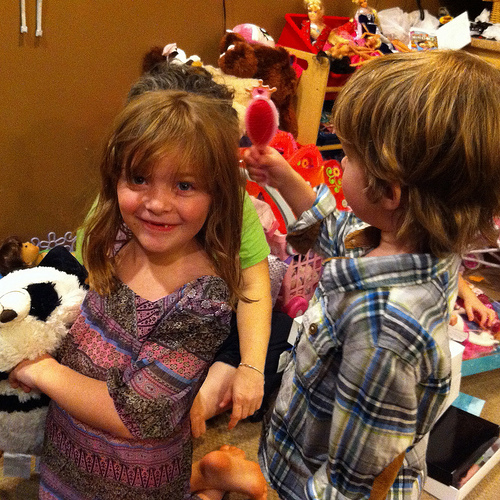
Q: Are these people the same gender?
A: No, they are both male and female.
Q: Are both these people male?
A: No, they are both male and female.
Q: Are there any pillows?
A: No, there are no pillows.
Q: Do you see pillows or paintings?
A: No, there are no pillows or paintings.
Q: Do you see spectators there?
A: No, there are no spectators.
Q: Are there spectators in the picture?
A: No, there are no spectators.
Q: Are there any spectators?
A: No, there are no spectators.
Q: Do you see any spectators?
A: No, there are no spectators.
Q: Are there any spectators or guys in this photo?
A: No, there are no spectators or guys.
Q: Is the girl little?
A: Yes, the girl is little.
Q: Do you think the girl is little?
A: Yes, the girl is little.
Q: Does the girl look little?
A: Yes, the girl is little.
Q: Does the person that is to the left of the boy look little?
A: Yes, the girl is little.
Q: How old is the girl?
A: The girl is little.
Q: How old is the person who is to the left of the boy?
A: The girl is little.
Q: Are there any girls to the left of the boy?
A: Yes, there is a girl to the left of the boy.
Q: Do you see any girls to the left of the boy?
A: Yes, there is a girl to the left of the boy.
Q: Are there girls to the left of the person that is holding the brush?
A: Yes, there is a girl to the left of the boy.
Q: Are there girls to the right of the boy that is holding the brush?
A: No, the girl is to the left of the boy.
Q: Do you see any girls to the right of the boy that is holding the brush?
A: No, the girl is to the left of the boy.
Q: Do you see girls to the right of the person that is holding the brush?
A: No, the girl is to the left of the boy.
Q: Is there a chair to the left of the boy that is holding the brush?
A: No, there is a girl to the left of the boy.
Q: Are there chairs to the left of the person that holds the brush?
A: No, there is a girl to the left of the boy.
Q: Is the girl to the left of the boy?
A: Yes, the girl is to the left of the boy.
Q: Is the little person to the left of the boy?
A: Yes, the girl is to the left of the boy.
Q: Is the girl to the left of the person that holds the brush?
A: Yes, the girl is to the left of the boy.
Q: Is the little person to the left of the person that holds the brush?
A: Yes, the girl is to the left of the boy.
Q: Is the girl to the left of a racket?
A: No, the girl is to the left of the boy.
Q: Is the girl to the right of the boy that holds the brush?
A: No, the girl is to the left of the boy.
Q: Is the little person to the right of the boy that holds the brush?
A: No, the girl is to the left of the boy.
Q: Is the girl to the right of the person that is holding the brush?
A: No, the girl is to the left of the boy.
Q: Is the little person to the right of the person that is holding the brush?
A: No, the girl is to the left of the boy.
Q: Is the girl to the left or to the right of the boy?
A: The girl is to the left of the boy.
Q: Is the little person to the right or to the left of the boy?
A: The girl is to the left of the boy.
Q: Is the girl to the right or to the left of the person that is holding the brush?
A: The girl is to the left of the boy.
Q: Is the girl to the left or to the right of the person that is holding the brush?
A: The girl is to the left of the boy.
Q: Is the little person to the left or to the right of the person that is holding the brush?
A: The girl is to the left of the boy.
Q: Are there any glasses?
A: No, there are no glasses.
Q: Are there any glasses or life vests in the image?
A: No, there are no glasses or life vests.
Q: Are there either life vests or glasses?
A: No, there are no glasses or life vests.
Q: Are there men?
A: No, there are no men.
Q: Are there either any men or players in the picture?
A: No, there are no men or players.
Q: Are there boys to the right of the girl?
A: Yes, there is a boy to the right of the girl.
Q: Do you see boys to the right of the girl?
A: Yes, there is a boy to the right of the girl.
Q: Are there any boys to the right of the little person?
A: Yes, there is a boy to the right of the girl.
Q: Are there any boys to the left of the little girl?
A: No, the boy is to the right of the girl.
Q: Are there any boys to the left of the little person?
A: No, the boy is to the right of the girl.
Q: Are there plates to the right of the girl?
A: No, there is a boy to the right of the girl.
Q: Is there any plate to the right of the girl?
A: No, there is a boy to the right of the girl.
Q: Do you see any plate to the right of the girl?
A: No, there is a boy to the right of the girl.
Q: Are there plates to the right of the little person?
A: No, there is a boy to the right of the girl.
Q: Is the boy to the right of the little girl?
A: Yes, the boy is to the right of the girl.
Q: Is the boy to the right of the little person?
A: Yes, the boy is to the right of the girl.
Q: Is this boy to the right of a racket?
A: No, the boy is to the right of the girl.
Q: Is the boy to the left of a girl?
A: No, the boy is to the right of a girl.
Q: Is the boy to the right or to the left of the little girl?
A: The boy is to the right of the girl.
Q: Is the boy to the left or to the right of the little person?
A: The boy is to the right of the girl.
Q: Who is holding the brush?
A: The boy is holding the brush.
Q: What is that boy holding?
A: The boy is holding the brush.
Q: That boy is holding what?
A: The boy is holding the brush.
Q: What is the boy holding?
A: The boy is holding the brush.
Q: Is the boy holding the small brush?
A: Yes, the boy is holding the brush.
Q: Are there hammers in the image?
A: No, there are no hammers.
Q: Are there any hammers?
A: No, there are no hammers.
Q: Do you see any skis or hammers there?
A: No, there are no hammers or skis.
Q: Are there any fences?
A: No, there are no fences.